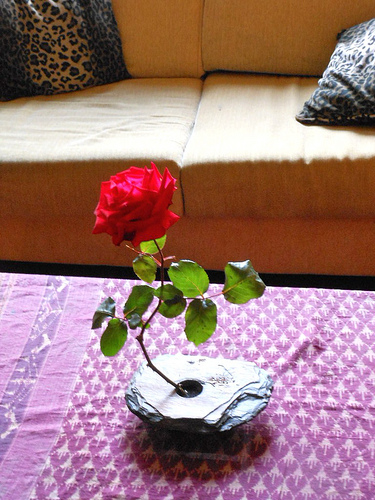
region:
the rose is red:
[88, 148, 176, 271]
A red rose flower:
[91, 166, 183, 245]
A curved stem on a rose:
[135, 239, 183, 391]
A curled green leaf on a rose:
[221, 261, 262, 303]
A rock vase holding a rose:
[125, 356, 275, 434]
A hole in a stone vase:
[174, 379, 202, 398]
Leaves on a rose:
[90, 301, 132, 352]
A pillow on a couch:
[293, 15, 373, 124]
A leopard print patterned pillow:
[1, 3, 126, 93]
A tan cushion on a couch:
[190, 71, 373, 221]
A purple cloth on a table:
[3, 273, 372, 498]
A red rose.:
[90, 160, 181, 246]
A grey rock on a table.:
[123, 353, 273, 436]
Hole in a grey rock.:
[173, 378, 202, 398]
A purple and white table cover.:
[1, 270, 373, 498]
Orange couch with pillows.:
[0, 0, 374, 279]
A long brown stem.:
[135, 239, 191, 397]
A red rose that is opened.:
[88, 159, 179, 249]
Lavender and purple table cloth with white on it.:
[0, 268, 373, 498]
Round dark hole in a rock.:
[174, 378, 202, 396]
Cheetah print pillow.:
[1, 0, 129, 104]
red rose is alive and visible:
[92, 160, 179, 244]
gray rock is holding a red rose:
[124, 352, 272, 432]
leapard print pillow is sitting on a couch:
[0, 0, 130, 97]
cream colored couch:
[1, 0, 373, 276]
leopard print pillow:
[296, 17, 373, 124]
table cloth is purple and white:
[1, 272, 373, 497]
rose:
[91, 161, 179, 247]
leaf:
[100, 318, 128, 357]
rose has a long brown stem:
[127, 242, 189, 396]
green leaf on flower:
[222, 260, 267, 308]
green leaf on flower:
[185, 298, 216, 347]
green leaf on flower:
[167, 259, 211, 295]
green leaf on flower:
[154, 283, 186, 321]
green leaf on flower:
[121, 280, 154, 319]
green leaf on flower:
[97, 318, 128, 360]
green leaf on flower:
[90, 294, 117, 331]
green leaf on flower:
[133, 253, 157, 286]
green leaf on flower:
[139, 234, 169, 255]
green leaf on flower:
[127, 314, 142, 332]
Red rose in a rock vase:
[89, 159, 274, 431]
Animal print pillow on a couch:
[1, 0, 134, 99]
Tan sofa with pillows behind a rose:
[1, 0, 372, 278]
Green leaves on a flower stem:
[87, 242, 264, 359]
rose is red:
[83, 161, 189, 258]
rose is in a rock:
[87, 159, 276, 447]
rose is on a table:
[80, 155, 313, 442]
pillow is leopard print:
[296, 14, 373, 140]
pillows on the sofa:
[2, 2, 373, 278]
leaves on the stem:
[93, 237, 267, 356]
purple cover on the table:
[0, 272, 373, 498]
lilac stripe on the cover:
[0, 270, 95, 498]